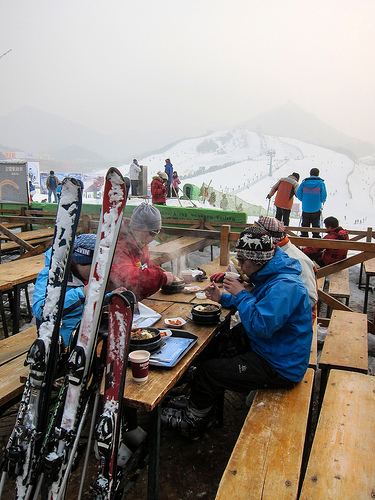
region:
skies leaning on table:
[6, 153, 165, 498]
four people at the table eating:
[30, 198, 331, 410]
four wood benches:
[192, 295, 374, 495]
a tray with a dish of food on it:
[108, 322, 208, 368]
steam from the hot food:
[119, 234, 212, 307]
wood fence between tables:
[12, 211, 367, 341]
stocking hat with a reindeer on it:
[227, 220, 284, 263]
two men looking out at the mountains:
[257, 162, 334, 257]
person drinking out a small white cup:
[206, 231, 295, 309]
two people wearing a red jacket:
[106, 168, 176, 293]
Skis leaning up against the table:
[28, 150, 124, 453]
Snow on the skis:
[54, 235, 109, 356]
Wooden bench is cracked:
[230, 426, 280, 497]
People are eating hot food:
[145, 214, 233, 330]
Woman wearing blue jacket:
[231, 240, 325, 393]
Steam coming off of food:
[116, 226, 223, 323]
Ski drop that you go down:
[189, 136, 289, 225]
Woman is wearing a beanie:
[128, 205, 193, 277]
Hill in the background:
[183, 85, 372, 151]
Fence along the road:
[331, 144, 374, 218]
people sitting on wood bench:
[224, 210, 322, 395]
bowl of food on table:
[191, 297, 223, 327]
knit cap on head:
[236, 224, 275, 266]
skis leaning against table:
[10, 276, 138, 480]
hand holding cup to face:
[218, 265, 244, 297]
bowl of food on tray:
[129, 321, 190, 366]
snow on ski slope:
[269, 144, 354, 167]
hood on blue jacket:
[266, 247, 302, 282]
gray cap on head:
[131, 196, 165, 236]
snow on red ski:
[111, 310, 127, 366]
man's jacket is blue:
[229, 264, 325, 407]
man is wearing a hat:
[226, 225, 293, 275]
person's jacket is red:
[114, 229, 165, 293]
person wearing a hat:
[128, 200, 169, 243]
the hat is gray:
[131, 203, 162, 235]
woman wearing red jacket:
[146, 175, 185, 210]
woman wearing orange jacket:
[270, 173, 295, 211]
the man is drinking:
[191, 210, 320, 398]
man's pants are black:
[196, 352, 311, 406]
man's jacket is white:
[128, 158, 143, 181]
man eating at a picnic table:
[225, 226, 311, 403]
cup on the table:
[131, 345, 162, 388]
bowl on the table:
[190, 295, 220, 333]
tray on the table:
[151, 323, 195, 366]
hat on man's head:
[234, 224, 282, 263]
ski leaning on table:
[105, 289, 132, 495]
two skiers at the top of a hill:
[268, 161, 330, 222]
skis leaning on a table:
[36, 156, 107, 496]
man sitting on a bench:
[316, 215, 350, 279]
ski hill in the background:
[212, 130, 321, 171]